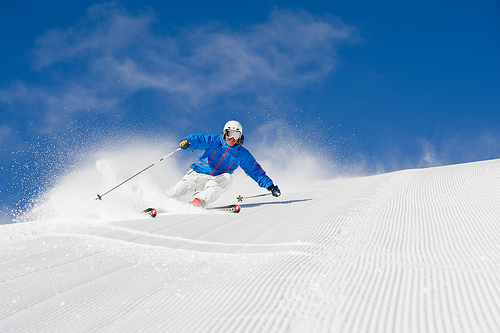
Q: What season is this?
A: Winter.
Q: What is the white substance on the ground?
A: Snow.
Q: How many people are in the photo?
A: One.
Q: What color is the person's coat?
A: Blue and red.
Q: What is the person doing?
A: Skiing.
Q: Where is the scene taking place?
A: On a ski slope.